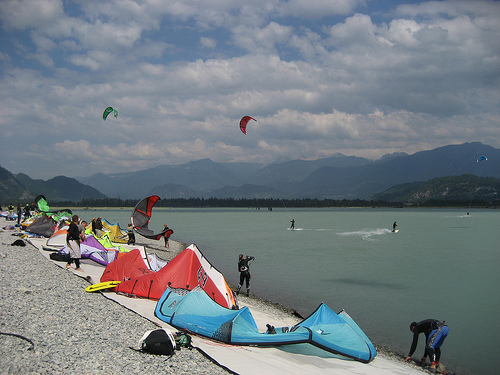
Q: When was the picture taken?
A: Daytime.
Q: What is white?
A: Clouds.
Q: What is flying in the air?
A: Kites.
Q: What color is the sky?
A: Blue.